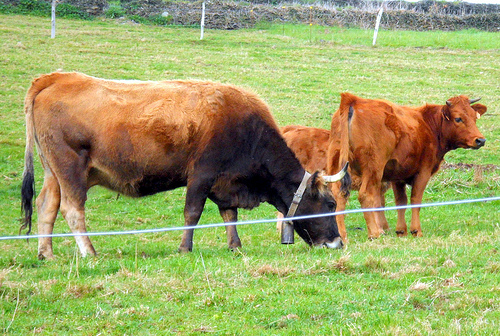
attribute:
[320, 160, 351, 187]
horn — pointed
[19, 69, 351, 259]
cow — brown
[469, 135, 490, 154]
nose — brown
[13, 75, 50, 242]
tail — down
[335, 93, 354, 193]
tail — down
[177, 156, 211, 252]
leg — brown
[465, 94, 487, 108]
horn — pointed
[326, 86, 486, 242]
cow — brown